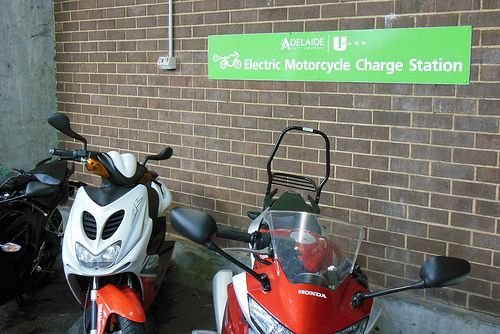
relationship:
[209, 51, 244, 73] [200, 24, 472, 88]
motorcycle on sign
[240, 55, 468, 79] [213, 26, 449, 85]
words on sign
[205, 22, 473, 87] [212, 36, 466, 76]
green sign with white lettering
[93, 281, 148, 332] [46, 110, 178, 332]
cover on bike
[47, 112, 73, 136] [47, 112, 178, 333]
mirror on motorcycle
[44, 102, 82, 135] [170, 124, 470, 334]
mirror on motorcycle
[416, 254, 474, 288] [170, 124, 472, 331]
mirrors on motorcycle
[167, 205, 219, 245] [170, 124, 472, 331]
mirrors on motorcycle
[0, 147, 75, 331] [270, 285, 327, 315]
motorcycle has detaling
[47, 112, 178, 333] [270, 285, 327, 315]
motorcycle has detaling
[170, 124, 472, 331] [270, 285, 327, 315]
motorcycle has detaling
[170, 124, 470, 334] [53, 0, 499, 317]
motorcycle near brick wall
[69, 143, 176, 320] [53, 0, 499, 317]
motorcycle near brick wall